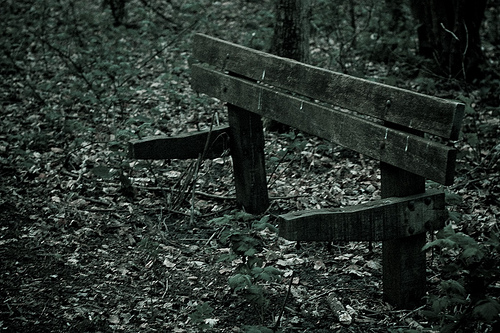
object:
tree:
[263, 0, 319, 131]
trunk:
[263, 0, 315, 133]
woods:
[0, 0, 500, 333]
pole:
[227, 67, 269, 216]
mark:
[261, 69, 267, 80]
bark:
[262, 0, 312, 133]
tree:
[403, 0, 491, 76]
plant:
[419, 214, 499, 332]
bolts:
[385, 100, 391, 107]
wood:
[126, 124, 235, 159]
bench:
[126, 32, 468, 300]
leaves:
[203, 316, 221, 326]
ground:
[0, 0, 497, 332]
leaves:
[252, 214, 271, 231]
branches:
[164, 121, 217, 211]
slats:
[190, 32, 465, 140]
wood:
[272, 191, 452, 244]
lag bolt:
[383, 99, 392, 115]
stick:
[101, 182, 312, 200]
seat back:
[188, 28, 464, 186]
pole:
[378, 116, 430, 311]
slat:
[190, 63, 457, 187]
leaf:
[162, 257, 176, 268]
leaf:
[162, 171, 181, 181]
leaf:
[195, 261, 206, 267]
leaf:
[68, 258, 79, 263]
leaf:
[123, 202, 132, 206]